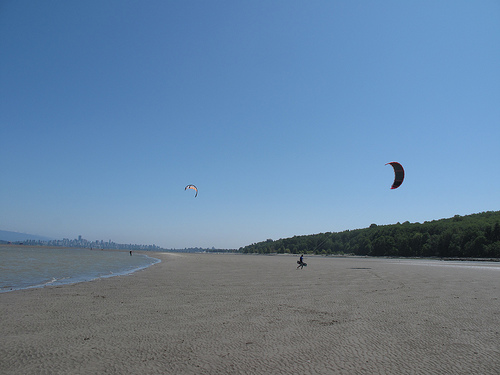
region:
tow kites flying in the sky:
[151, 137, 420, 229]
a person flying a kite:
[273, 138, 413, 297]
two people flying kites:
[106, 147, 425, 292]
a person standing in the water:
[111, 232, 148, 292]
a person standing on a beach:
[280, 244, 336, 300]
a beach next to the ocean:
[3, 242, 250, 325]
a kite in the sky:
[113, 176, 204, 287]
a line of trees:
[251, 211, 491, 266]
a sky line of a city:
[38, 233, 165, 257]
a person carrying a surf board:
[293, 245, 313, 278]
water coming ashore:
[108, 245, 149, 290]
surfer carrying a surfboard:
[293, 252, 309, 278]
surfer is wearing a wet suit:
[299, 256, 305, 269]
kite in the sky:
[374, 140, 429, 200]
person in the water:
[110, 243, 150, 264]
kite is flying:
[162, 168, 218, 200]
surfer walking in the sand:
[283, 249, 321, 275]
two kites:
[162, 160, 411, 200]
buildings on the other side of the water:
[68, 228, 112, 252]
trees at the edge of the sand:
[371, 215, 435, 280]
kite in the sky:
[379, 149, 407, 203]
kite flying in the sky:
[180, 177, 207, 198]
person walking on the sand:
[290, 246, 315, 276]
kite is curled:
[378, 153, 410, 195]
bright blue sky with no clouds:
[1, 1, 499, 246]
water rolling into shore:
[2, 236, 160, 313]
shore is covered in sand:
[2, 241, 494, 369]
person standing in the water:
[122, 246, 138, 260]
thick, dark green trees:
[234, 209, 499, 254]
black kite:
[380, 156, 408, 191]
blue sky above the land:
[161, 38, 263, 105]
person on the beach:
[286, 243, 321, 283]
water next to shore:
[60, 250, 102, 289]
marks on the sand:
[195, 288, 275, 352]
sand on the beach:
[153, 270, 233, 342]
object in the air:
[353, 147, 422, 214]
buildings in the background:
[53, 224, 102, 265]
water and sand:
[106, 259, 148, 294]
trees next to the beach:
[378, 226, 418, 263]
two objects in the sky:
[163, 130, 433, 231]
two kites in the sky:
[171, 148, 416, 220]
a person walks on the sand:
[290, 248, 313, 275]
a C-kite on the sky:
[376, 145, 413, 200]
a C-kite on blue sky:
[174, 171, 214, 205]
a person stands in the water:
[103, 242, 182, 291]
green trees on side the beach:
[10, 206, 499, 367]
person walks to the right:
[281, 245, 323, 277]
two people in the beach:
[0, 234, 489, 368]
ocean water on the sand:
[1, 240, 236, 335]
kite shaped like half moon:
[368, 145, 421, 205]